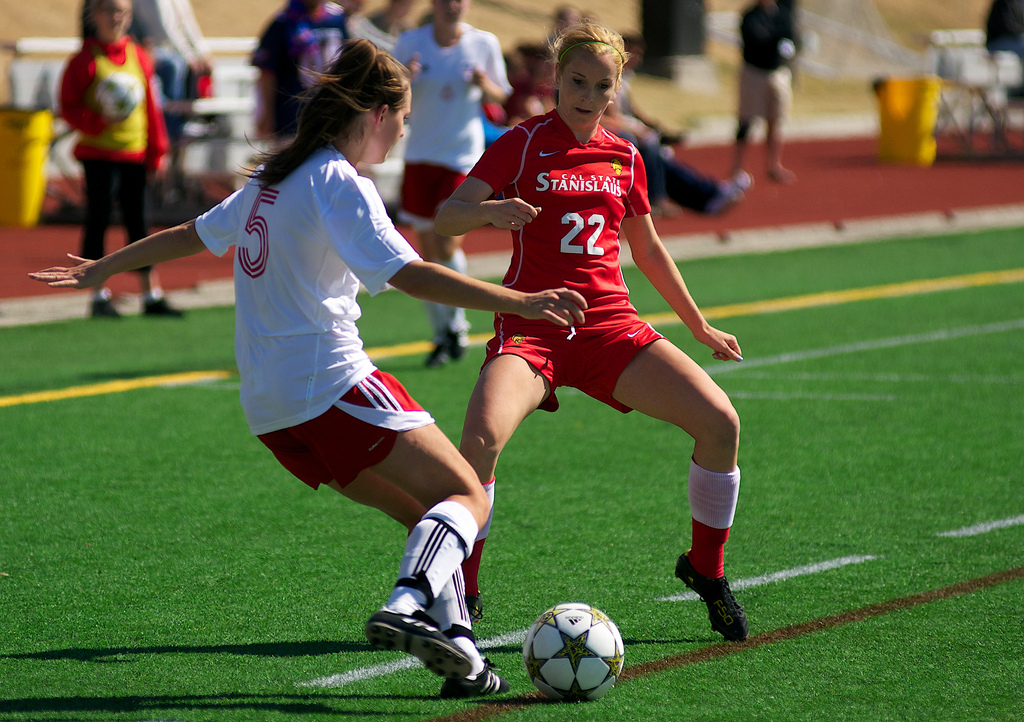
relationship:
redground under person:
[773, 144, 932, 239] [731, 8, 798, 186]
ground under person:
[13, 140, 1022, 315] [731, 8, 798, 186]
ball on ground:
[482, 559, 661, 712] [7, 225, 1021, 714]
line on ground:
[844, 552, 980, 650] [7, 225, 1021, 714]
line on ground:
[778, 520, 892, 609] [7, 225, 1021, 714]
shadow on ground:
[83, 592, 236, 714] [7, 225, 1021, 714]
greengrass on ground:
[800, 394, 957, 493] [7, 225, 1021, 714]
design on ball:
[550, 614, 596, 664] [515, 584, 639, 714]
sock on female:
[679, 454, 747, 584] [404, 0, 783, 656]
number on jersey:
[226, 175, 293, 301] [172, 137, 433, 442]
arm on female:
[415, 131, 530, 269] [404, 0, 783, 656]